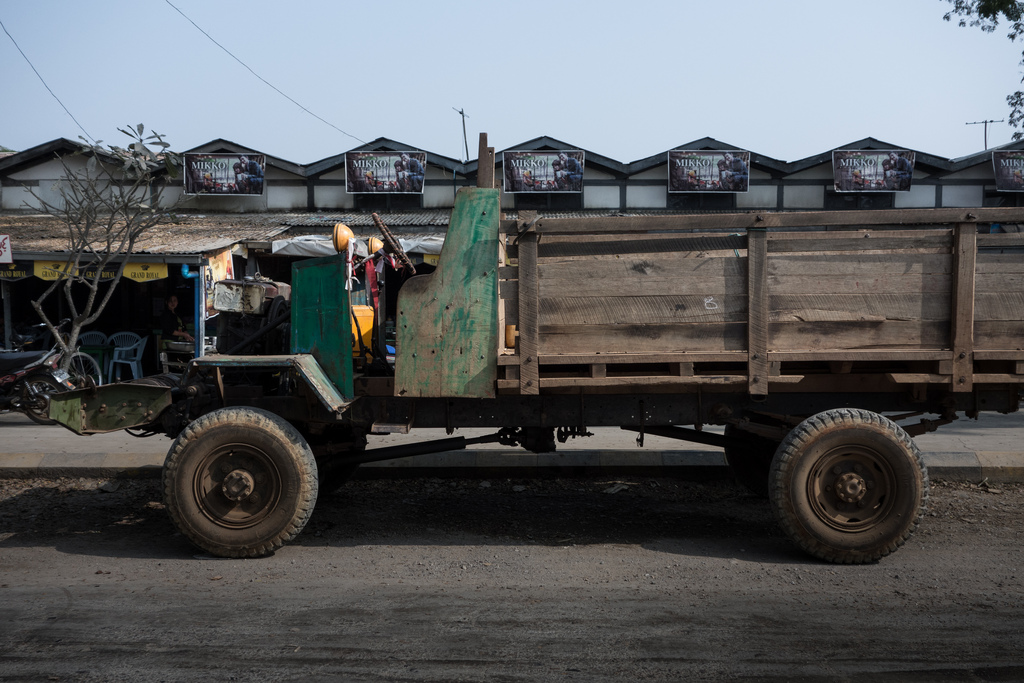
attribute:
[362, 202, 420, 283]
steering wheel — brown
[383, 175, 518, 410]
door — green, side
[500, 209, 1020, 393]
truck bed — wood